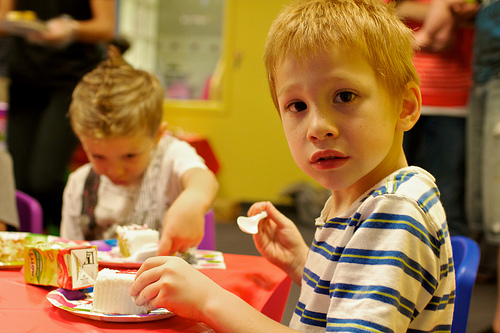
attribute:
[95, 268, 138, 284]
frosting — white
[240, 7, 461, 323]
boy — blonde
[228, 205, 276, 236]
spoon — plastic, white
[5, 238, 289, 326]
table — red, orange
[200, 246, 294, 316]
tablecloth — red, plastic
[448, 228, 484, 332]
chair — plastic, blue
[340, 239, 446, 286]
stripes — white, yellow, blue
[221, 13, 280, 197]
wall — yellow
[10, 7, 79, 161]
clothes — black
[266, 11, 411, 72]
hair — blonde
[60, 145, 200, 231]
shirt — white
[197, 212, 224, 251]
chair — purple